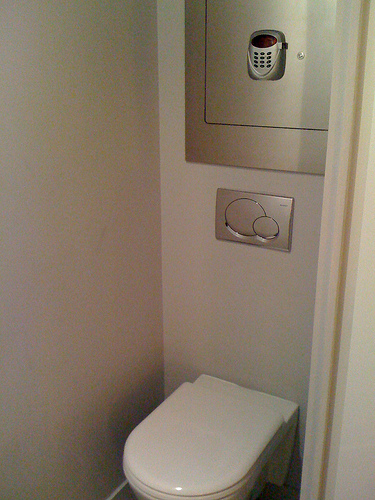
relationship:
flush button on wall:
[192, 184, 312, 252] [172, 145, 302, 360]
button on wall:
[259, 59, 264, 63] [155, 1, 336, 489]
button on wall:
[266, 50, 271, 55] [155, 1, 336, 489]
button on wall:
[266, 63, 272, 67] [155, 1, 336, 489]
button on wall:
[253, 63, 258, 67] [155, 1, 336, 489]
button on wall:
[253, 50, 258, 55] [155, 1, 336, 489]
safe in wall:
[168, 1, 331, 177] [156, 1, 363, 416]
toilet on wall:
[118, 371, 298, 499] [168, 170, 309, 381]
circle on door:
[292, 48, 307, 61] [198, 1, 335, 136]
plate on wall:
[225, 189, 267, 248] [167, 75, 366, 371]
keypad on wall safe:
[246, 25, 288, 81] [181, 2, 336, 176]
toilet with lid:
[118, 371, 298, 499] [102, 373, 290, 495]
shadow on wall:
[114, 367, 184, 412] [21, 127, 184, 392]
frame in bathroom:
[299, 0, 374, 498] [2, 3, 374, 497]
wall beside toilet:
[0, 8, 162, 495] [118, 371, 298, 499]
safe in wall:
[184, 1, 333, 178] [155, 1, 336, 489]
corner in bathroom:
[149, 0, 170, 400] [2, 3, 374, 497]